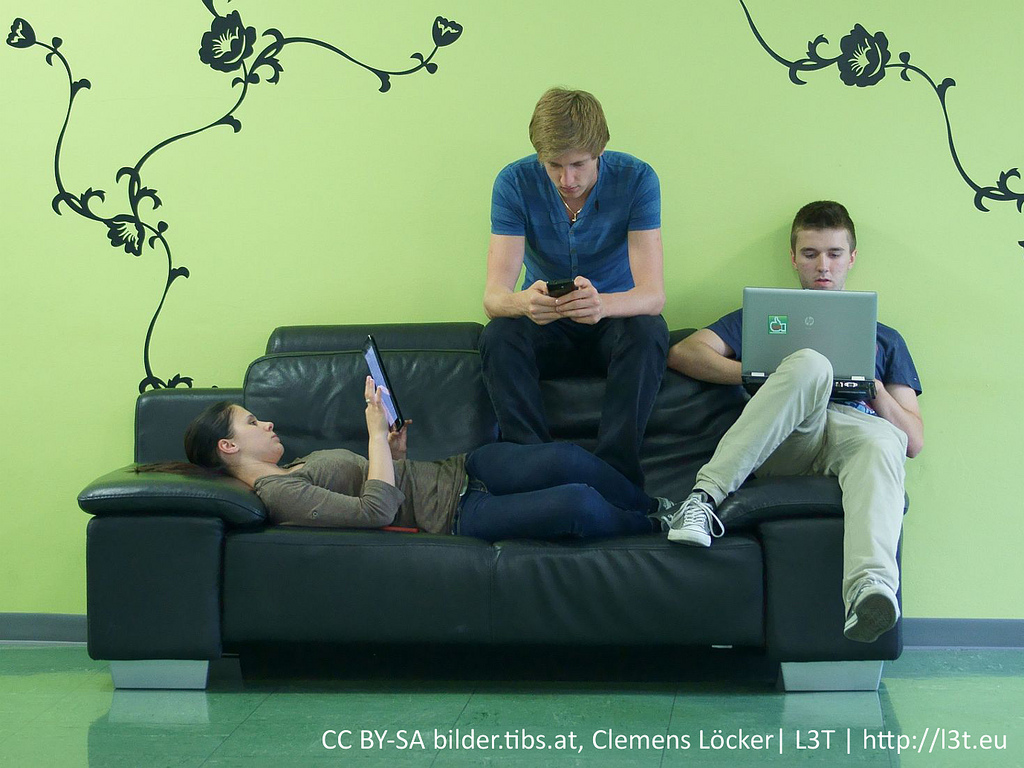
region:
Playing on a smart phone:
[490, 86, 652, 461]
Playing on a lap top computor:
[667, 218, 921, 646]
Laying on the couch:
[183, 364, 671, 564]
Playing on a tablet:
[190, 335, 674, 567]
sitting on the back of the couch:
[483, 86, 677, 460]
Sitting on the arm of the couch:
[717, 199, 923, 648]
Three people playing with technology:
[124, 82, 922, 677]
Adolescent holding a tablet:
[186, 373, 681, 579]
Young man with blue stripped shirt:
[479, 85, 660, 452]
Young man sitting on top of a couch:
[480, 82, 687, 532]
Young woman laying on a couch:
[192, 367, 699, 560]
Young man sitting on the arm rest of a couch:
[672, 195, 936, 649]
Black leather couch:
[98, 315, 909, 714]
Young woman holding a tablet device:
[167, 328, 725, 560]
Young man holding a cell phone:
[483, 83, 684, 508]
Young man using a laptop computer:
[678, 186, 931, 657]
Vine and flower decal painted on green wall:
[719, 2, 1013, 269]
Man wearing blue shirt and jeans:
[479, 83, 691, 516]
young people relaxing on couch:
[73, 77, 927, 689]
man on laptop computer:
[670, 196, 926, 640]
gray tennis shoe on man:
[661, 485, 722, 549]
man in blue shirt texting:
[482, 80, 675, 464]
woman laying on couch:
[132, 332, 674, 558]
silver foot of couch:
[100, 650, 217, 696]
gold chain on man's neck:
[555, 185, 590, 223]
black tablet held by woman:
[357, 323, 409, 432]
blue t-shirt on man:
[480, 149, 661, 309]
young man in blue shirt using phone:
[474, 84, 668, 490]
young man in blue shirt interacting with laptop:
[663, 196, 926, 646]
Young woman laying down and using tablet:
[125, 324, 685, 549]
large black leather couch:
[73, 321, 911, 692]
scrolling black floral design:
[5, 0, 1023, 393]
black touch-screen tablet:
[357, 326, 406, 434]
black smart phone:
[544, 277, 576, 296]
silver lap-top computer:
[739, 283, 882, 401]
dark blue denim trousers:
[449, 435, 659, 543]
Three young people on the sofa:
[75, 83, 929, 697]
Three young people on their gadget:
[71, 81, 928, 693]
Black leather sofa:
[75, 319, 910, 699]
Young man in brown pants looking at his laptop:
[656, 194, 923, 644]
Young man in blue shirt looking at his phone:
[472, 81, 672, 484]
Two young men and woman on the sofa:
[68, 81, 928, 696]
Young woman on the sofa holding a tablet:
[122, 327, 673, 544]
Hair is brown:
[526, 81, 609, 162]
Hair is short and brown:
[785, 198, 855, 257]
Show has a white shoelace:
[661, 486, 726, 550]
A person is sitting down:
[477, 98, 665, 469]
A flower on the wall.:
[9, 20, 44, 52]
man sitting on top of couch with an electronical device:
[477, 82, 678, 476]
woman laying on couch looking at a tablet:
[178, 373, 678, 542]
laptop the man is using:
[728, 284, 884, 401]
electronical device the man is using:
[542, 278, 580, 307]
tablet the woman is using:
[346, 332, 405, 434]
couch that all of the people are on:
[71, 309, 913, 705]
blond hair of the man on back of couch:
[528, 87, 608, 158]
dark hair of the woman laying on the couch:
[137, 398, 242, 482]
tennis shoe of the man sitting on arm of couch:
[665, 489, 723, 550]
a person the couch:
[456, 54, 694, 438]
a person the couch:
[125, 369, 549, 663]